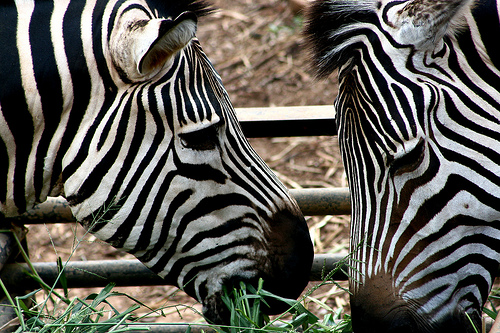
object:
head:
[58, 0, 315, 333]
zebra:
[0, 0, 315, 333]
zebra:
[295, 0, 498, 333]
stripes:
[94, 82, 140, 152]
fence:
[0, 103, 353, 294]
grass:
[0, 286, 349, 333]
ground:
[21, 0, 347, 333]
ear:
[128, 10, 200, 76]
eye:
[176, 118, 224, 151]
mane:
[293, 0, 371, 86]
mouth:
[198, 278, 288, 333]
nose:
[263, 206, 317, 299]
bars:
[288, 185, 354, 217]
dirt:
[254, 215, 292, 272]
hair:
[152, 19, 195, 52]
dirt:
[185, 0, 337, 108]